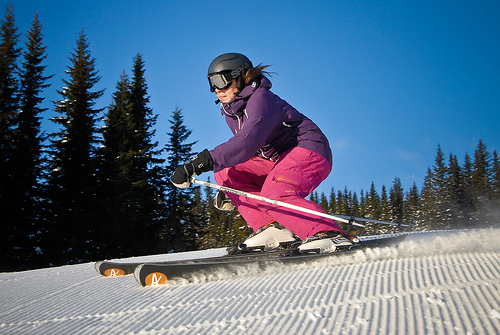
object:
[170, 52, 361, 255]
girl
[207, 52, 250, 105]
helmet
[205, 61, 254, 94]
goggles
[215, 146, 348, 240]
pants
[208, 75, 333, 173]
jacket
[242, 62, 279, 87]
hair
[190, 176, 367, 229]
pole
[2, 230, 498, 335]
snow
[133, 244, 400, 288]
skis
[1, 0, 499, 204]
sky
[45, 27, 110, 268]
trees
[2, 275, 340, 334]
tracks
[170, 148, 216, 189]
glove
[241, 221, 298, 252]
boot